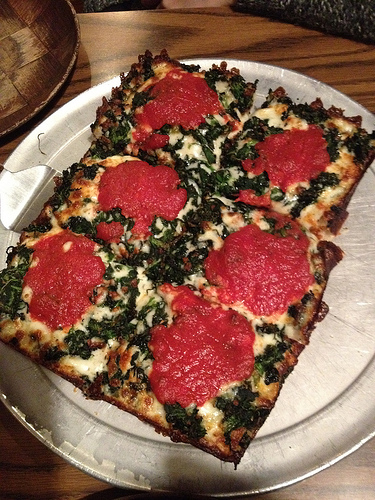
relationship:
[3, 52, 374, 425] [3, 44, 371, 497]
spinach on pizza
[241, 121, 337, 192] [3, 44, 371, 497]
sauce on pizza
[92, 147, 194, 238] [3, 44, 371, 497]
sauce on pizza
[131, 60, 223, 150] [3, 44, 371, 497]
sauce on pizza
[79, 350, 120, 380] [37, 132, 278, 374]
cheese on pizza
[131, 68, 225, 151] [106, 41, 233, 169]
sauce on pizza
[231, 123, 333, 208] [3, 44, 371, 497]
sauce on pizza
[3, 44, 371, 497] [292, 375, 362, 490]
pizza on a baking pan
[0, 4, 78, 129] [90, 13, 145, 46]
bowl on table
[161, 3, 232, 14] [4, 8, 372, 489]
hand resting against table